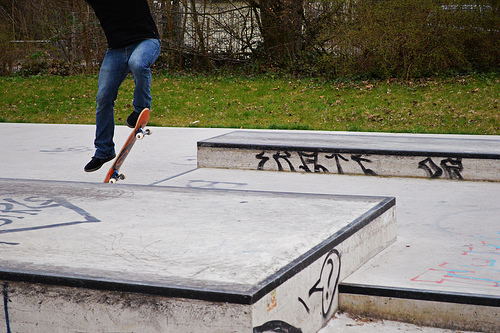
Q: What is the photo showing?
A: It is showing a skate park.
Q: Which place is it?
A: It is a skate park.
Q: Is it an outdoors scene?
A: Yes, it is outdoors.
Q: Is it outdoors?
A: Yes, it is outdoors.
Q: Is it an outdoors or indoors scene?
A: It is outdoors.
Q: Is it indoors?
A: No, it is outdoors.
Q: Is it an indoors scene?
A: No, it is outdoors.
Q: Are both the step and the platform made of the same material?
A: Yes, both the step and the platform are made of concrete.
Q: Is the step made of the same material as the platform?
A: Yes, both the step and the platform are made of concrete.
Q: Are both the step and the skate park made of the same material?
A: Yes, both the step and the skate park are made of cement.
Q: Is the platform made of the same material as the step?
A: Yes, both the platform and the step are made of concrete.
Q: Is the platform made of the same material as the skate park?
A: Yes, both the platform and the skate park are made of cement.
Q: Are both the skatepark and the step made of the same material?
A: Yes, both the skatepark and the step are made of concrete.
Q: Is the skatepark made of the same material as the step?
A: Yes, both the skatepark and the step are made of concrete.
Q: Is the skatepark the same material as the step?
A: Yes, both the skatepark and the step are made of concrete.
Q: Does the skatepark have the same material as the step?
A: Yes, both the skatepark and the step are made of concrete.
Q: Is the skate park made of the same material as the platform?
A: Yes, both the skate park and the platform are made of concrete.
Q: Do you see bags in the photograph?
A: No, there are no bags.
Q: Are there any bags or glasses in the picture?
A: No, there are no bags or glasses.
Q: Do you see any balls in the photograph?
A: No, there are no balls.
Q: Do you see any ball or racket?
A: No, there are no balls or rackets.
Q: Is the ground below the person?
A: Yes, the ground is below the person.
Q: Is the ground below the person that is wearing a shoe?
A: Yes, the ground is below the person.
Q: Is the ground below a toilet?
A: No, the ground is below the person.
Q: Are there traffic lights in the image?
A: No, there are no traffic lights.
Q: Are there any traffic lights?
A: No, there are no traffic lights.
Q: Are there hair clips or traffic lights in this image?
A: No, there are no traffic lights or hair clips.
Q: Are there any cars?
A: No, there are no cars.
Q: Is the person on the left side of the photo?
A: Yes, the person is on the left of the image.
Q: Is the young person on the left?
A: Yes, the person is on the left of the image.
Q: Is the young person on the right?
A: No, the person is on the left of the image.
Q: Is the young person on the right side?
A: No, the person is on the left of the image.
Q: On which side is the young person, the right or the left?
A: The person is on the left of the image.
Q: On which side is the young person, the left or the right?
A: The person is on the left of the image.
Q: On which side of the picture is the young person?
A: The person is on the left of the image.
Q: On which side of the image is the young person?
A: The person is on the left of the image.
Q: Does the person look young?
A: Yes, the person is young.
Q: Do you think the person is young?
A: Yes, the person is young.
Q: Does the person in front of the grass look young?
A: Yes, the person is young.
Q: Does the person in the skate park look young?
A: Yes, the person is young.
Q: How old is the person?
A: The person is young.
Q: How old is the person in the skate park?
A: The person is young.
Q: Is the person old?
A: No, the person is young.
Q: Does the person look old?
A: No, the person is young.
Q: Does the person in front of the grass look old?
A: No, the person is young.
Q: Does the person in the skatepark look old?
A: No, the person is young.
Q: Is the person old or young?
A: The person is young.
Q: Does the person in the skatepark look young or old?
A: The person is young.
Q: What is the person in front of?
A: The person is in front of the grass.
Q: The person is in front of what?
A: The person is in front of the grass.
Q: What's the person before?
A: The person is in front of the grass.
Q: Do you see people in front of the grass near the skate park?
A: Yes, there is a person in front of the grass.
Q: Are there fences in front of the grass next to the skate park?
A: No, there is a person in front of the grass.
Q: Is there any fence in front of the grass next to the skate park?
A: No, there is a person in front of the grass.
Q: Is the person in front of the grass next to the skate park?
A: Yes, the person is in front of the grass.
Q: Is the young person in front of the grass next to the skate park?
A: Yes, the person is in front of the grass.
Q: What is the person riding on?
A: The person is riding on a skateboard.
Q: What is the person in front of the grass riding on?
A: The person is riding on a skateboard.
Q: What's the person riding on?
A: The person is riding on a skateboard.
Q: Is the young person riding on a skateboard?
A: Yes, the person is riding on a skateboard.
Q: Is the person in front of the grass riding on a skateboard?
A: Yes, the person is riding on a skateboard.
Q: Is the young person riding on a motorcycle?
A: No, the person is riding on a skateboard.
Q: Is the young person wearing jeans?
A: Yes, the person is wearing jeans.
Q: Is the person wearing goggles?
A: No, the person is wearing jeans.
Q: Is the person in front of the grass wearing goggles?
A: No, the person is wearing jeans.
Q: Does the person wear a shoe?
A: Yes, the person wears a shoe.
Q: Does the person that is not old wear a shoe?
A: Yes, the person wears a shoe.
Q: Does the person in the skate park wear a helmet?
A: No, the person wears a shoe.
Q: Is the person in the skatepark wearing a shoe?
A: Yes, the person is wearing a shoe.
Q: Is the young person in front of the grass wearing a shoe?
A: Yes, the person is wearing a shoe.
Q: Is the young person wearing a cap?
A: No, the person is wearing a shoe.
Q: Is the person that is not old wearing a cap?
A: No, the person is wearing a shoe.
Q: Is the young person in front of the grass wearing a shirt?
A: Yes, the person is wearing a shirt.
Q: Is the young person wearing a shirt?
A: Yes, the person is wearing a shirt.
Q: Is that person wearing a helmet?
A: No, the person is wearing a shirt.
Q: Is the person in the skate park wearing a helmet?
A: No, the person is wearing a shirt.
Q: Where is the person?
A: The person is in the skate park.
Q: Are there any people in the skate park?
A: Yes, there is a person in the skate park.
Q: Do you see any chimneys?
A: No, there are no chimneys.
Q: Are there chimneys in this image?
A: No, there are no chimneys.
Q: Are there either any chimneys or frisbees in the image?
A: No, there are no chimneys or frisbees.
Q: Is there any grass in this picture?
A: Yes, there is grass.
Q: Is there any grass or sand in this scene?
A: Yes, there is grass.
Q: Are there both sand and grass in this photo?
A: No, there is grass but no sand.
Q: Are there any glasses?
A: No, there are no glasses.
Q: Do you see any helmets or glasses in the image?
A: No, there are no glasses or helmets.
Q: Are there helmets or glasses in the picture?
A: No, there are no glasses or helmets.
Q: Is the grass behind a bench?
A: No, the grass is behind the person.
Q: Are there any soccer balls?
A: No, there are no soccer balls.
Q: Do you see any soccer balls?
A: No, there are no soccer balls.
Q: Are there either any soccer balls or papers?
A: No, there are no soccer balls or papers.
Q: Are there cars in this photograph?
A: No, there are no cars.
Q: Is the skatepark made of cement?
A: Yes, the skatepark is made of cement.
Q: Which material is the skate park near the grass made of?
A: The skate park is made of cement.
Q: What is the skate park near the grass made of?
A: The skate park is made of cement.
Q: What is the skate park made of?
A: The skate park is made of concrete.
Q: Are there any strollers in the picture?
A: No, there are no strollers.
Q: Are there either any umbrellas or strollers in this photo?
A: No, there are no strollers or umbrellas.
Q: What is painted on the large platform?
A: The graffiti is painted on the platform.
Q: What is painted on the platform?
A: The graffiti is painted on the platform.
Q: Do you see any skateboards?
A: Yes, there is a skateboard.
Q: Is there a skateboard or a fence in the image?
A: Yes, there is a skateboard.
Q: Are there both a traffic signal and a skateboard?
A: No, there is a skateboard but no traffic lights.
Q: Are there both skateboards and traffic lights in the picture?
A: No, there is a skateboard but no traffic lights.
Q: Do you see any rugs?
A: No, there are no rugs.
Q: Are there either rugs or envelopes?
A: No, there are no rugs or envelopes.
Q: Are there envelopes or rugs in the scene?
A: No, there are no rugs or envelopes.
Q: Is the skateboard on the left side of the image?
A: Yes, the skateboard is on the left of the image.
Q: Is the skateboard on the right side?
A: No, the skateboard is on the left of the image.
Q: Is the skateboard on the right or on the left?
A: The skateboard is on the left of the image.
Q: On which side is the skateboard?
A: The skateboard is on the left of the image.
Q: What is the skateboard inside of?
A: The skateboard is inside the skate park.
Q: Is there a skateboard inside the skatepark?
A: Yes, there is a skateboard inside the skatepark.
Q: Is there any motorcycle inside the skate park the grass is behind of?
A: No, there is a skateboard inside the skate park.